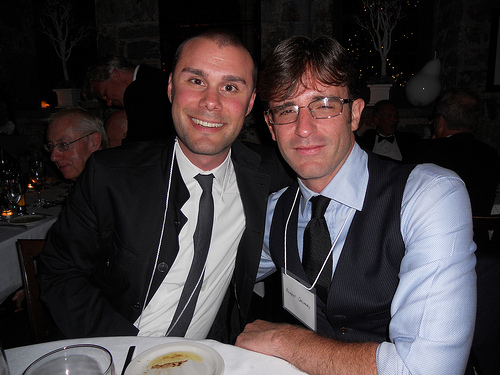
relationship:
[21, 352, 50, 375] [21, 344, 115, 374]
rim of glass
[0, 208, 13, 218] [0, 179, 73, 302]
candle on table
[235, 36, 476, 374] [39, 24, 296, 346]
man friends with man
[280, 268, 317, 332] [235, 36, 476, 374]
tag on man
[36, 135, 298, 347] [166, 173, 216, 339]
suit and tie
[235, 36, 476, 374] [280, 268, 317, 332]
man wearing a tag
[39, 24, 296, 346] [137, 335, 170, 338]
man wearing a tag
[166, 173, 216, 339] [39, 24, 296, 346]
tie on man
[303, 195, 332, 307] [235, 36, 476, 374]
tie on man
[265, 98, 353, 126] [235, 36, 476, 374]
glasses on man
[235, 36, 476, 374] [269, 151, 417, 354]
man wearing vest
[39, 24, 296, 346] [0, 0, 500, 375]
man at wedding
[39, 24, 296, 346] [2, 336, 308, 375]
man sitting at table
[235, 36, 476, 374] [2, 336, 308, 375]
man sitting at table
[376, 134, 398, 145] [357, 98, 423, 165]
bow tie on man